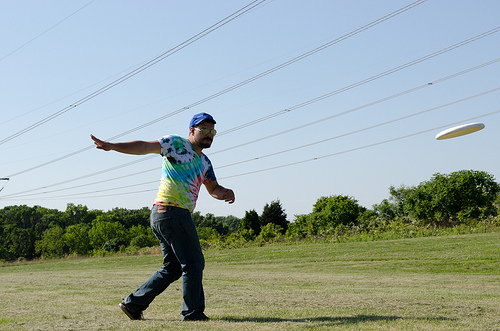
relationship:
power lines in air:
[0, 0, 499, 197] [1, 0, 484, 222]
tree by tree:
[1, 203, 70, 258] [36, 199, 98, 265]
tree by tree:
[36, 199, 98, 265] [87, 205, 131, 255]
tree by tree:
[87, 205, 131, 255] [125, 201, 170, 251]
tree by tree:
[125, 201, 170, 251] [193, 206, 241, 251]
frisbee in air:
[396, 98, 493, 147] [1, 0, 484, 222]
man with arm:
[88, 111, 234, 321] [89, 135, 158, 155]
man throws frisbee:
[88, 111, 234, 321] [424, 108, 487, 150]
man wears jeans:
[88, 111, 234, 321] [116, 199, 209, 321]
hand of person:
[89, 134, 111, 152] [80, 100, 260, 315]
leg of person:
[157, 217, 214, 321] [90, 112, 235, 321]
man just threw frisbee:
[77, 92, 261, 309] [413, 94, 493, 161]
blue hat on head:
[188, 112, 217, 129] [188, 111, 217, 151]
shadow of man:
[206, 314, 458, 330] [126, 109, 286, 303]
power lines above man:
[0, 0, 499, 197] [84, 112, 232, 317]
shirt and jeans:
[151, 134, 217, 211] [124, 204, 207, 313]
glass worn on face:
[195, 125, 217, 136] [187, 117, 217, 149]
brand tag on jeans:
[150, 201, 167, 213] [116, 199, 209, 321]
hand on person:
[87, 131, 114, 156] [90, 112, 235, 321]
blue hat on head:
[188, 112, 217, 129] [189, 112, 215, 147]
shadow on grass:
[218, 303, 401, 328] [304, 231, 499, 288]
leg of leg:
[118, 223, 182, 321] [133, 227, 182, 302]